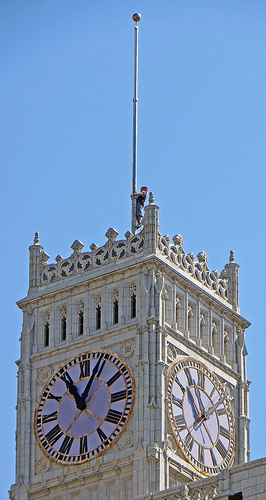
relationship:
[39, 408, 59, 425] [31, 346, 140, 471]
roman numeral on clock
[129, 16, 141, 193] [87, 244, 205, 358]
pole on building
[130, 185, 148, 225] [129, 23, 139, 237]
person holding pole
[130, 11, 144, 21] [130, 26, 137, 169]
ball atop flagpole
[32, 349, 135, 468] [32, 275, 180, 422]
clock on tower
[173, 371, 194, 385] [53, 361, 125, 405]
numerals on clock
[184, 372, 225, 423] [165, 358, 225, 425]
hands on clock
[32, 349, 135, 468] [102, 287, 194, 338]
clock on building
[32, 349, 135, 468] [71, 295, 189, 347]
clock on building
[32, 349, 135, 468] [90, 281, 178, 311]
clock on tower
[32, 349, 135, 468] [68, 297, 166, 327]
clock on tower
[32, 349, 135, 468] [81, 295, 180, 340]
clock on building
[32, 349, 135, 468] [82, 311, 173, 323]
clock on building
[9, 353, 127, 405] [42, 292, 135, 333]
clock on tower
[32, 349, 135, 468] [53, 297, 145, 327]
clock on tower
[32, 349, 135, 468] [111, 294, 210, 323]
clock on building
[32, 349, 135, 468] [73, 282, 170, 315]
clock on tower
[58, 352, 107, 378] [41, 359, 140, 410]
numeral on clock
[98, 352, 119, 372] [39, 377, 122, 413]
numeral on clock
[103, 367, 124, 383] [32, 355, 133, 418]
numeral on clock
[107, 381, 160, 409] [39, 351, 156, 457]
numeral on clock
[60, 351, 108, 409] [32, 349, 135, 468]
hands on clock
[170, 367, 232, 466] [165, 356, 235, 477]
numbers on clock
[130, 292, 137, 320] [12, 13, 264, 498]
window on tower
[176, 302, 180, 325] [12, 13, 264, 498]
window on tower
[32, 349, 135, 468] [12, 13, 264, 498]
clock on tower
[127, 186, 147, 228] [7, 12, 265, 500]
person on building